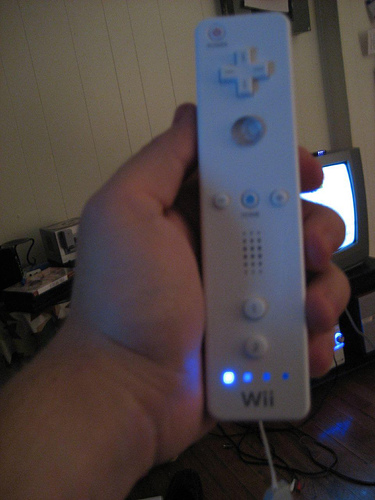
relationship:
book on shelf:
[5, 264, 75, 295] [1, 236, 80, 321]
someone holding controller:
[0, 101, 350, 498] [186, 17, 313, 421]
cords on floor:
[210, 417, 375, 500] [122, 364, 369, 497]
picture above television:
[218, 2, 316, 36] [285, 143, 371, 272]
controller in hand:
[186, 17, 313, 421] [65, 97, 353, 455]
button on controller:
[206, 25, 231, 43] [186, 17, 313, 421]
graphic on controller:
[240, 388, 275, 409] [190, 14, 311, 423]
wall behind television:
[14, 19, 104, 181] [286, 147, 365, 280]